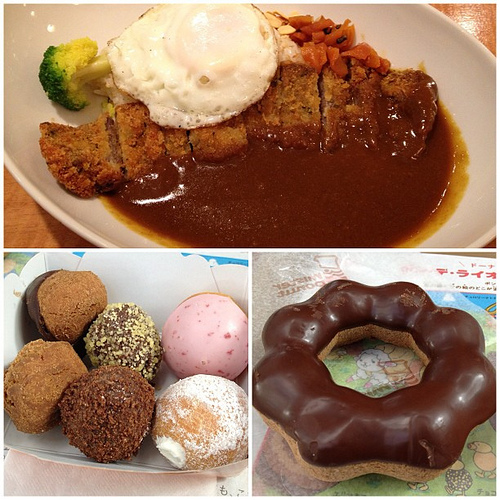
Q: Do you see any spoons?
A: No, there are no spoons.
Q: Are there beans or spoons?
A: No, there are no spoons or beans.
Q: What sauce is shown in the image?
A: The sauce is gravy.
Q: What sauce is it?
A: The sauce is gravy.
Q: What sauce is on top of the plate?
A: The sauce is gravy.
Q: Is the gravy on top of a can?
A: No, the gravy is on top of a plate.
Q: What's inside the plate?
A: The gravy is inside the plate.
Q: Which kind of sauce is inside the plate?
A: The sauce is gravy.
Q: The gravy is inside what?
A: The gravy is inside the plate.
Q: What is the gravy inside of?
A: The gravy is inside the plate.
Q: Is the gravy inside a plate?
A: Yes, the gravy is inside a plate.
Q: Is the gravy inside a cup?
A: No, the gravy is inside a plate.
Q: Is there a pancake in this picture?
A: No, there are no pancakes.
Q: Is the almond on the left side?
A: Yes, the almond is on the left of the image.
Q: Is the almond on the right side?
A: No, the almond is on the left of the image.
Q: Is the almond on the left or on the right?
A: The almond is on the left of the image.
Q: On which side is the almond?
A: The almond is on the left of the image.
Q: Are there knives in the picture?
A: No, there are no knives.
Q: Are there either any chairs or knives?
A: No, there are no knives or chairs.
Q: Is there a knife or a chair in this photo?
A: No, there are no knives or chairs.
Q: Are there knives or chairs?
A: No, there are no knives or chairs.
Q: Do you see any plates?
A: Yes, there is a plate.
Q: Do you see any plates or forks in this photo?
A: Yes, there is a plate.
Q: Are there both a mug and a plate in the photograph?
A: No, there is a plate but no mugs.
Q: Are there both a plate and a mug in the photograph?
A: No, there is a plate but no mugs.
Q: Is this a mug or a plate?
A: This is a plate.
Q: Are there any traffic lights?
A: No, there are no traffic lights.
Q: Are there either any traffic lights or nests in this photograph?
A: No, there are no traffic lights or nests.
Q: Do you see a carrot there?
A: Yes, there are carrots.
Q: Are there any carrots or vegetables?
A: Yes, there are carrots.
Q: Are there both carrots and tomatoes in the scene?
A: No, there are carrots but no tomatoes.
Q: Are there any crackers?
A: No, there are no crackers.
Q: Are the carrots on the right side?
A: Yes, the carrots are on the right of the image.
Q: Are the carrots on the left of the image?
A: No, the carrots are on the right of the image.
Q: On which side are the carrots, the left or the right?
A: The carrots are on the right of the image.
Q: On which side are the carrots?
A: The carrots are on the right of the image.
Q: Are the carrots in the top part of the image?
A: Yes, the carrots are in the top of the image.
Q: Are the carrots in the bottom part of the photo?
A: No, the carrots are in the top of the image.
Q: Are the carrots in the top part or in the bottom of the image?
A: The carrots are in the top of the image.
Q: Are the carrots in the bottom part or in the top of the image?
A: The carrots are in the top of the image.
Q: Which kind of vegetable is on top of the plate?
A: The vegetables are carrots.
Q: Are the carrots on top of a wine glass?
A: No, the carrots are on top of the plate.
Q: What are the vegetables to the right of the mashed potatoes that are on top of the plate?
A: The vegetables are carrots.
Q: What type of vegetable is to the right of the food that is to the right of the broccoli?
A: The vegetables are carrots.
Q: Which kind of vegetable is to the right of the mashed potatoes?
A: The vegetables are carrots.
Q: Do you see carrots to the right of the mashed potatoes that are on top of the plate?
A: Yes, there are carrots to the right of the mashed potatoes.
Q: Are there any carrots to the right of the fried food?
A: Yes, there are carrots to the right of the mashed potatoes.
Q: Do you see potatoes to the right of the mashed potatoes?
A: No, there are carrots to the right of the mashed potatoes.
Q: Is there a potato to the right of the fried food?
A: No, there are carrots to the right of the mashed potatoes.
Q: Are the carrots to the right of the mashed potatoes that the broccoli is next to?
A: Yes, the carrots are to the right of the mashed potatoes.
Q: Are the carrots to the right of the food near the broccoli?
A: Yes, the carrots are to the right of the mashed potatoes.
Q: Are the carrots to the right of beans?
A: No, the carrots are to the right of the mashed potatoes.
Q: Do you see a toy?
A: No, there are no toys.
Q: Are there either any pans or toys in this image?
A: No, there are no toys or pans.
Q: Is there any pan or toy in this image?
A: No, there are no toys or pans.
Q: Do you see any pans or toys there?
A: No, there are no toys or pans.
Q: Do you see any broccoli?
A: Yes, there is broccoli.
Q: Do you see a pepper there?
A: No, there are no peppers.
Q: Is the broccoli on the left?
A: Yes, the broccoli is on the left of the image.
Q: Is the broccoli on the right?
A: No, the broccoli is on the left of the image.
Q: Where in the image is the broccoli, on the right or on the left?
A: The broccoli is on the left of the image.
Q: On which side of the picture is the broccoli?
A: The broccoli is on the left of the image.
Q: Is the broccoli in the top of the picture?
A: Yes, the broccoli is in the top of the image.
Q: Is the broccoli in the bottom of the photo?
A: No, the broccoli is in the top of the image.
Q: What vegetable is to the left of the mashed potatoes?
A: The vegetable is broccoli.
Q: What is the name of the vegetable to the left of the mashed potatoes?
A: The vegetable is broccoli.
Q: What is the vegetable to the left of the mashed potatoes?
A: The vegetable is broccoli.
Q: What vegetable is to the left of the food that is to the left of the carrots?
A: The vegetable is broccoli.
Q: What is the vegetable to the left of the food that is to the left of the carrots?
A: The vegetable is broccoli.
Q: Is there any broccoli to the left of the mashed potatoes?
A: Yes, there is broccoli to the left of the mashed potatoes.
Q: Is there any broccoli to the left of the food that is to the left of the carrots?
A: Yes, there is broccoli to the left of the mashed potatoes.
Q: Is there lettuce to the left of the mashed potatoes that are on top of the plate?
A: No, there is broccoli to the left of the mashed potatoes.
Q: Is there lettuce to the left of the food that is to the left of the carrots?
A: No, there is broccoli to the left of the mashed potatoes.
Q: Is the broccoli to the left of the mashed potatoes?
A: Yes, the broccoli is to the left of the mashed potatoes.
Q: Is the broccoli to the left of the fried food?
A: Yes, the broccoli is to the left of the mashed potatoes.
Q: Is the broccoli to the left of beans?
A: No, the broccoli is to the left of the mashed potatoes.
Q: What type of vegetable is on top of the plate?
A: The vegetable is broccoli.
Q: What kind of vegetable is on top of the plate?
A: The vegetable is broccoli.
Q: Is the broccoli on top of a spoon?
A: No, the broccoli is on top of the plate.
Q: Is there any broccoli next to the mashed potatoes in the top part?
A: Yes, there is broccoli next to the mashed potatoes.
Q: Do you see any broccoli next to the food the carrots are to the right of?
A: Yes, there is broccoli next to the mashed potatoes.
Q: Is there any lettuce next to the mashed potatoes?
A: No, there is broccoli next to the mashed potatoes.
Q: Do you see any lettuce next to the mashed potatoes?
A: No, there is broccoli next to the mashed potatoes.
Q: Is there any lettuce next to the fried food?
A: No, there is broccoli next to the mashed potatoes.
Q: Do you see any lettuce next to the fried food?
A: No, there is broccoli next to the mashed potatoes.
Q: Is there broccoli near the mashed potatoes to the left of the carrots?
A: Yes, there is broccoli near the mashed potatoes.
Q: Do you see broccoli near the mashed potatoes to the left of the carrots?
A: Yes, there is broccoli near the mashed potatoes.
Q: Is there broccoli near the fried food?
A: Yes, there is broccoli near the mashed potatoes.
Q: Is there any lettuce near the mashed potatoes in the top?
A: No, there is broccoli near the mashed potatoes.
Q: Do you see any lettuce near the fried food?
A: No, there is broccoli near the mashed potatoes.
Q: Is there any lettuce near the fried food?
A: No, there is broccoli near the mashed potatoes.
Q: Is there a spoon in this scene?
A: No, there are no spoons.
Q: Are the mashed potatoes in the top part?
A: Yes, the mashed potatoes are in the top of the image.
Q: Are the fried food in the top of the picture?
A: Yes, the mashed potatoes are in the top of the image.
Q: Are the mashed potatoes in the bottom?
A: No, the mashed potatoes are in the top of the image.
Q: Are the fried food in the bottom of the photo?
A: No, the mashed potatoes are in the top of the image.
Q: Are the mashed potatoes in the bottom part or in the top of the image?
A: The mashed potatoes are in the top of the image.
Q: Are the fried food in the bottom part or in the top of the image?
A: The mashed potatoes are in the top of the image.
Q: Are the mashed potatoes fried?
A: Yes, the mashed potatoes are fried.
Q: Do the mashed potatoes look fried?
A: Yes, the mashed potatoes are fried.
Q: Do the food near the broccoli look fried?
A: Yes, the mashed potatoes are fried.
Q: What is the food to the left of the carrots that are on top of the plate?
A: The food is mashed potatoes.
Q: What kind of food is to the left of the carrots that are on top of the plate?
A: The food is mashed potatoes.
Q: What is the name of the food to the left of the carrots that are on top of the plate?
A: The food is mashed potatoes.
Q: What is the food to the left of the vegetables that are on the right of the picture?
A: The food is mashed potatoes.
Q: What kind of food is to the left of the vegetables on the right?
A: The food is mashed potatoes.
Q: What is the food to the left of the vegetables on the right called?
A: The food is mashed potatoes.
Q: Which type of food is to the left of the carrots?
A: The food is mashed potatoes.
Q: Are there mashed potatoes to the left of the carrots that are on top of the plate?
A: Yes, there are mashed potatoes to the left of the carrots.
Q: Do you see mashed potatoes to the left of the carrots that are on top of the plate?
A: Yes, there are mashed potatoes to the left of the carrots.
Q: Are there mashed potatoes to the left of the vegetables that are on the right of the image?
A: Yes, there are mashed potatoes to the left of the carrots.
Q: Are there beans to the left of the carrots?
A: No, there are mashed potatoes to the left of the carrots.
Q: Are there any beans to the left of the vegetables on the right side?
A: No, there are mashed potatoes to the left of the carrots.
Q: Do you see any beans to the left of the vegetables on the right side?
A: No, there are mashed potatoes to the left of the carrots.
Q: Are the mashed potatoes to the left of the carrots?
A: Yes, the mashed potatoes are to the left of the carrots.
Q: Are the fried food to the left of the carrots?
A: Yes, the mashed potatoes are to the left of the carrots.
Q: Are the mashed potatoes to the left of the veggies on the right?
A: Yes, the mashed potatoes are to the left of the carrots.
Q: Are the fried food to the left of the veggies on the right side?
A: Yes, the mashed potatoes are to the left of the carrots.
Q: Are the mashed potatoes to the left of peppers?
A: No, the mashed potatoes are to the left of the carrots.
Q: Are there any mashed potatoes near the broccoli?
A: Yes, there are mashed potatoes near the broccoli.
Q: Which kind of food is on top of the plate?
A: The food is mashed potatoes.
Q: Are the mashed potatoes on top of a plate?
A: Yes, the mashed potatoes are on top of a plate.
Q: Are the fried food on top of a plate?
A: Yes, the mashed potatoes are on top of a plate.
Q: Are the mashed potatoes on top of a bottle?
A: No, the mashed potatoes are on top of a plate.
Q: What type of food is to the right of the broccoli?
A: The food is mashed potatoes.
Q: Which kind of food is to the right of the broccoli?
A: The food is mashed potatoes.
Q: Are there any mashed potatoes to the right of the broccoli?
A: Yes, there are mashed potatoes to the right of the broccoli.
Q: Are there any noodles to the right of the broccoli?
A: No, there are mashed potatoes to the right of the broccoli.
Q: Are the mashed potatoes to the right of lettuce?
A: No, the mashed potatoes are to the right of the broccoli.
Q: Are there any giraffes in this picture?
A: No, there are no giraffes.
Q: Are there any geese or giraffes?
A: No, there are no giraffes or geese.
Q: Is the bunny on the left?
A: No, the bunny is on the right of the image.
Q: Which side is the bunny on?
A: The bunny is on the right of the image.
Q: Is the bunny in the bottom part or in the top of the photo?
A: The bunny is in the bottom of the image.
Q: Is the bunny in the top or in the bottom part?
A: The bunny is in the bottom of the image.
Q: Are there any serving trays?
A: No, there are no serving trays.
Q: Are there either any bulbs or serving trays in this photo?
A: No, there are no serving trays or bulbs.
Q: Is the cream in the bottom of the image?
A: Yes, the cream is in the bottom of the image.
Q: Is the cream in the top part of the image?
A: No, the cream is in the bottom of the image.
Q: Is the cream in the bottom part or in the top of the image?
A: The cream is in the bottom of the image.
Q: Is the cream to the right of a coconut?
A: Yes, the cream is to the right of a coconut.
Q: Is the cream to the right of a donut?
A: No, the cream is to the right of a coconut.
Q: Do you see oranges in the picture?
A: No, there are no oranges.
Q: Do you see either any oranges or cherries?
A: No, there are no oranges or cherries.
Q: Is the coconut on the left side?
A: Yes, the coconut is on the left of the image.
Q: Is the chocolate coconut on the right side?
A: No, the coconut is on the left of the image.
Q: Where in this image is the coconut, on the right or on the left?
A: The coconut is on the left of the image.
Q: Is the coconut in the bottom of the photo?
A: Yes, the coconut is in the bottom of the image.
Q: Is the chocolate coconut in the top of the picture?
A: No, the coconut is in the bottom of the image.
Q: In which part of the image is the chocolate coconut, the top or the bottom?
A: The coconut is in the bottom of the image.